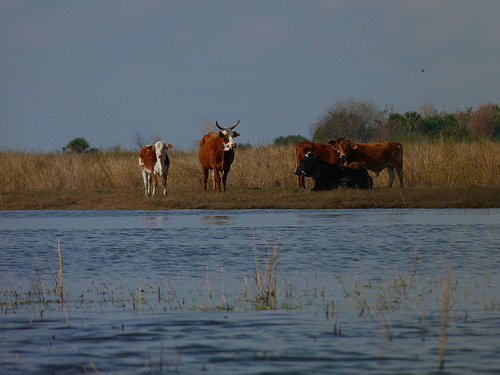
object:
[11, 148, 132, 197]
grass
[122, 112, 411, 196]
cows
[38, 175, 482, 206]
river bed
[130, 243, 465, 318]
plants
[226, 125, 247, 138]
ears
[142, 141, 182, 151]
ears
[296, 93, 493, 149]
trees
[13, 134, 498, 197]
grass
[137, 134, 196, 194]
cow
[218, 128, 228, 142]
spot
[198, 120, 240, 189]
cow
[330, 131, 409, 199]
cow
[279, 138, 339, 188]
cow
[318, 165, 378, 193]
cow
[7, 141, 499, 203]
land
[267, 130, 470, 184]
reeds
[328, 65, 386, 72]
airplane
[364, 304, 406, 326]
ufo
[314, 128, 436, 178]
clump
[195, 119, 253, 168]
expression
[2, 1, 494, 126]
sky is blue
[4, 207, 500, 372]
water is blue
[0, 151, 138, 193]
grass is brown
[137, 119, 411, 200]
cows are standing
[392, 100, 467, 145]
trees are green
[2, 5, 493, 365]
day time picture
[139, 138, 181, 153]
two pointed ears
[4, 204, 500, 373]
ocean is beautiful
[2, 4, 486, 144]
clear blue sky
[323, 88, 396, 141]
trees are dark brown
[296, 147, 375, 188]
black cow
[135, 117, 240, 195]
cows look at water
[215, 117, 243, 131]
horns sticking up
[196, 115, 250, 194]
cow has a spot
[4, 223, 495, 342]
grass sticking out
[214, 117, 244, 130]
cow's horns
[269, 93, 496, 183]
group of trees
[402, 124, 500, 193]
tall brown grass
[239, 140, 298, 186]
grass near  cows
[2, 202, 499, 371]
water is visible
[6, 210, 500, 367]
body of water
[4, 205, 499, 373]
large body of water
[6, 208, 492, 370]
mass of still water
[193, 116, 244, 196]
animal has horns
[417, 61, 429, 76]
small bird,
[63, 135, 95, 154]
bushy tree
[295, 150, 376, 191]
darker animal sits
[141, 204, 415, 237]
reflection of cows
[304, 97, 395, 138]
huge dry tree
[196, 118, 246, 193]
middle cattle figure